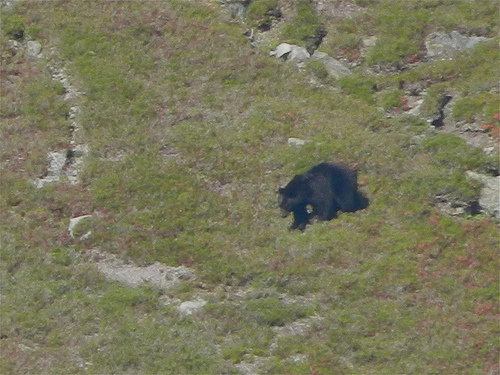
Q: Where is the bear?
A: In the field.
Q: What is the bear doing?
A: Walking.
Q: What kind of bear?
A: Wild.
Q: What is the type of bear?
A: Black bear.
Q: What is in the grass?
A: Gravel and rock.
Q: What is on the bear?
A: Fur.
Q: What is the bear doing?
A: Walking.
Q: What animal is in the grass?
A: Bear.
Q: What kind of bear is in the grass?
A: Black bear.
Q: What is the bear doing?
A: Walking.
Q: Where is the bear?
A: Field.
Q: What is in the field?
A: Dirt patches.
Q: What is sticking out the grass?
A: Rocks.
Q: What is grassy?
A: A hill.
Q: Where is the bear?
A: Grass.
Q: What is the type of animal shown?
A: Bear.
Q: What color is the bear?
A: Black.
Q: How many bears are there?
A: 1.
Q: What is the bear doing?
A: Walking.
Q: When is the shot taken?
A: Daytime.